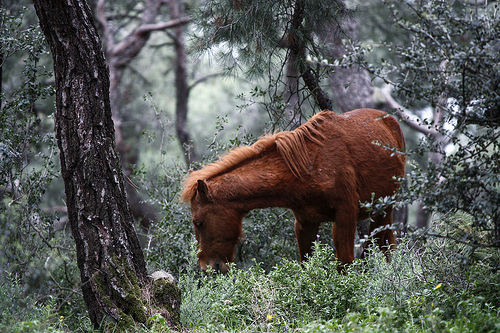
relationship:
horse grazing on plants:
[178, 108, 407, 276] [187, 243, 309, 316]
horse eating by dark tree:
[178, 108, 407, 276] [29, 3, 186, 331]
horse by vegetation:
[182, 100, 409, 287] [141, 192, 498, 331]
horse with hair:
[182, 100, 409, 287] [183, 112, 328, 202]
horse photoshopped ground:
[178, 108, 407, 276] [433, 148, 458, 186]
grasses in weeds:
[203, 272, 241, 312] [416, 272, 466, 315]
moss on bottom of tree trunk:
[96, 269, 154, 331] [30, 1, 182, 331]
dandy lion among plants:
[266, 314, 272, 320] [178, 233, 499, 330]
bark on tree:
[37, 5, 184, 333] [29, 4, 178, 332]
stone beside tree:
[145, 267, 183, 330] [29, 4, 178, 332]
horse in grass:
[178, 108, 407, 276] [5, 269, 499, 329]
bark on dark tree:
[37, 5, 185, 329] [29, 3, 186, 331]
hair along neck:
[183, 112, 328, 202] [204, 151, 290, 219]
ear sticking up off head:
[197, 178, 212, 203] [181, 167, 242, 275]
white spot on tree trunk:
[97, 182, 112, 207] [30, 1, 177, 333]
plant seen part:
[204, 246, 389, 328] [348, 255, 377, 275]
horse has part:
[178, 108, 407, 276] [188, 199, 208, 244]